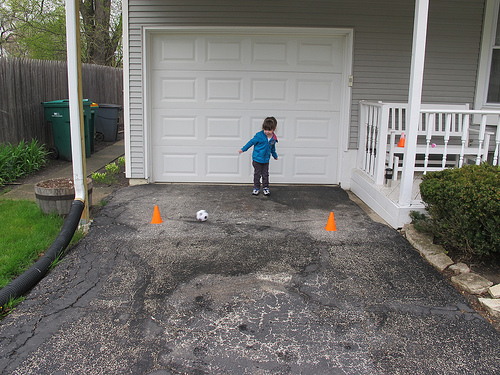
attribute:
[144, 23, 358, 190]
door — white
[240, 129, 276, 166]
jacket — blue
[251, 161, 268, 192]
pants — grey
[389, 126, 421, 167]
cone — orange, small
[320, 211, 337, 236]
pylon — orange, small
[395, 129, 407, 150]
cone — small, orange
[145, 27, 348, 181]
garage door — white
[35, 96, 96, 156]
trashcans — green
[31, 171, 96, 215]
planter — brown, circle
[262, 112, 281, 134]
hair — brown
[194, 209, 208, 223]
soccer ball — small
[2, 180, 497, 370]
driveway — long, gray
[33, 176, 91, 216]
planter — huge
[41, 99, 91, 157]
bin — green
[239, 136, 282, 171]
jacket — blue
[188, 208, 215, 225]
ball — small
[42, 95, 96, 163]
trashcan — large, green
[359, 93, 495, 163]
handrail — white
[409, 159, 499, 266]
bush — small, green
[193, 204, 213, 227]
ball — small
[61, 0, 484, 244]
house — gray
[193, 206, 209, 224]
soccer ball — black, white